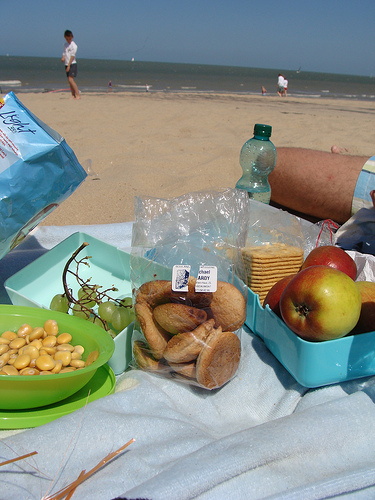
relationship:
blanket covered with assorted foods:
[0, 214, 364, 497] [9, 195, 369, 409]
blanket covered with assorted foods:
[0, 214, 364, 497] [1, 199, 374, 422]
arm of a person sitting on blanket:
[252, 145, 375, 224] [0, 214, 364, 497]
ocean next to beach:
[16, 19, 374, 102] [5, 74, 362, 224]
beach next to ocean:
[16, 85, 371, 200] [5, 49, 370, 110]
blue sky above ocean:
[1, 1, 374, 71] [0, 55, 374, 101]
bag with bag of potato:
[131, 188, 246, 391] [0, 90, 88, 259]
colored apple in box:
[263, 246, 375, 340] [229, 252, 357, 387]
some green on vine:
[296, 329, 374, 398] [54, 239, 125, 320]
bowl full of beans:
[2, 302, 119, 409] [0, 319, 99, 375]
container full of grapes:
[3, 231, 172, 376] [51, 240, 138, 336]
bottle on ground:
[235, 123, 277, 204] [4, 92, 363, 478]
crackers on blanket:
[239, 238, 303, 309] [0, 214, 364, 497]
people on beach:
[276, 73, 288, 97] [2, 88, 373, 228]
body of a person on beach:
[61, 29, 81, 100] [2, 88, 373, 228]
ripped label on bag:
[166, 252, 240, 298] [131, 188, 246, 391]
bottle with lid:
[232, 121, 274, 203] [251, 121, 274, 140]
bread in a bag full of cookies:
[128, 187, 250, 276] [127, 278, 239, 386]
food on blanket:
[6, 238, 356, 385] [0, 214, 364, 497]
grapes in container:
[50, 242, 137, 339] [6, 231, 172, 376]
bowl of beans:
[0, 304, 115, 410] [3, 319, 84, 377]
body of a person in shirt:
[61, 29, 81, 100] [60, 42, 79, 67]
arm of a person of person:
[61, 44, 94, 81] [58, 27, 80, 100]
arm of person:
[58, 43, 67, 62] [58, 27, 80, 100]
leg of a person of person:
[60, 73, 96, 107] [57, 26, 83, 105]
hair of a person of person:
[64, 29, 74, 43] [58, 24, 85, 100]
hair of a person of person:
[54, 21, 93, 42] [59, 27, 83, 100]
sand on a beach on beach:
[231, 112, 371, 254] [2, 88, 373, 228]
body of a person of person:
[57, 43, 90, 77] [58, 24, 85, 100]